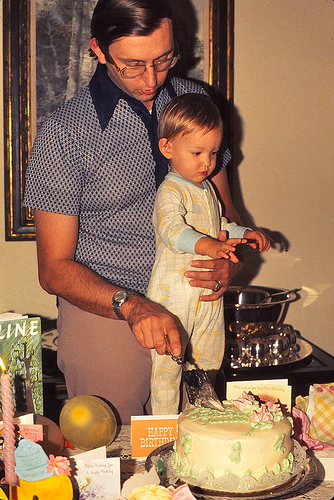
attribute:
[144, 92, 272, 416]
baby — light skinned, child, standing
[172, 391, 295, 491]
cake — brown, green, white, creamy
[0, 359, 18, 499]
candle — partial, pink, spiraled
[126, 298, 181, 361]
right hand — hairy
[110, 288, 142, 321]
watch —  wrist , metallic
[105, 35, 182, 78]
glasses — spectacle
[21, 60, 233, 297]
shirt — black, white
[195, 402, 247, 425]
icing — green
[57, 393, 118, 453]
balloon — yellow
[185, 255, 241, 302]
hand — hairy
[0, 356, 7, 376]
flame — partial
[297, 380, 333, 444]
cloth — partial